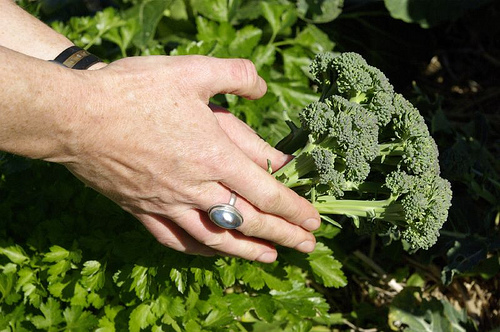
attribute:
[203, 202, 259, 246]
ring — silver, black, oval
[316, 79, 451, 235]
broccoli — green, flower, fresh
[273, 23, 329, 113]
leaves — green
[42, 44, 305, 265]
hands — together, white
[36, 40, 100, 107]
watch — green, silver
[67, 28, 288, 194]
person — gardening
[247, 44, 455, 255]
plants — green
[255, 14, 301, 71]
leaf — dead